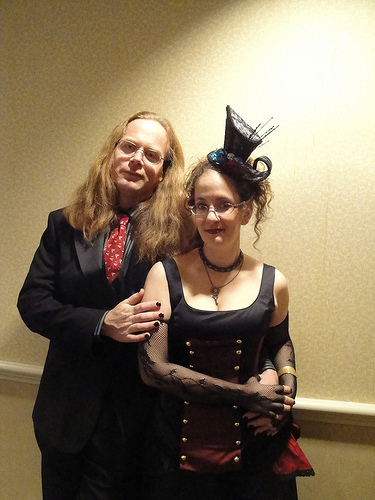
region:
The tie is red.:
[102, 214, 132, 282]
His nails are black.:
[135, 286, 165, 340]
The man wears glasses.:
[118, 137, 165, 165]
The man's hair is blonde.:
[64, 111, 194, 262]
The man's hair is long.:
[64, 111, 194, 262]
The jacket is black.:
[16, 196, 206, 456]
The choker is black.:
[197, 242, 244, 275]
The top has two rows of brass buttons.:
[180, 336, 243, 471]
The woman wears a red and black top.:
[151, 257, 317, 478]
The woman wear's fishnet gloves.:
[135, 310, 297, 435]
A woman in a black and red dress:
[136, 102, 319, 497]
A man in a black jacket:
[11, 106, 198, 496]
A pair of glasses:
[112, 135, 164, 165]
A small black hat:
[206, 101, 270, 179]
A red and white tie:
[100, 212, 130, 275]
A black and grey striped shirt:
[93, 204, 142, 332]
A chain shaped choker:
[196, 242, 241, 268]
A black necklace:
[195, 245, 243, 301]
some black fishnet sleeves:
[135, 309, 293, 416]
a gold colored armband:
[277, 364, 298, 376]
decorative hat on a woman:
[205, 96, 277, 196]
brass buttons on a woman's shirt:
[172, 326, 245, 476]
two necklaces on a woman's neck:
[195, 247, 246, 315]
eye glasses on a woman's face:
[185, 187, 239, 228]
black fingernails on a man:
[140, 297, 167, 346]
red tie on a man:
[97, 212, 134, 290]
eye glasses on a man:
[113, 139, 165, 171]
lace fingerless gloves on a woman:
[132, 308, 305, 434]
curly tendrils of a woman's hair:
[233, 170, 275, 266]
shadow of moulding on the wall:
[293, 403, 374, 453]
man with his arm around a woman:
[16, 110, 313, 499]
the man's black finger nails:
[137, 287, 164, 339]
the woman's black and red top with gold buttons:
[155, 260, 315, 476]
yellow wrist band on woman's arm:
[280, 365, 295, 376]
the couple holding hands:
[241, 369, 300, 435]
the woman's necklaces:
[199, 247, 245, 304]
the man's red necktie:
[105, 211, 130, 276]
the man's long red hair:
[68, 108, 188, 256]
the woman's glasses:
[185, 201, 248, 212]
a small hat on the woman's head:
[208, 103, 273, 184]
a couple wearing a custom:
[10, 91, 317, 496]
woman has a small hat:
[158, 94, 297, 295]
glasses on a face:
[175, 197, 244, 222]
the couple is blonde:
[36, 92, 307, 325]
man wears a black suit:
[10, 100, 183, 499]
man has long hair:
[35, 94, 201, 283]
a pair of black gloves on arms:
[125, 303, 308, 429]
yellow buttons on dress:
[172, 333, 251, 472]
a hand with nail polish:
[96, 280, 169, 353]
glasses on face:
[115, 132, 170, 173]